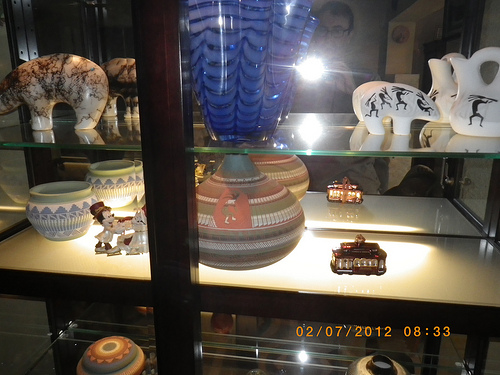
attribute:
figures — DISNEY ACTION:
[22, 51, 484, 160]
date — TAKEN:
[292, 315, 454, 347]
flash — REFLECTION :
[289, 45, 341, 85]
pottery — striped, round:
[192, 155, 303, 286]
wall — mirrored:
[18, 2, 471, 372]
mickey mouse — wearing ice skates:
[90, 199, 127, 258]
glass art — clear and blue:
[186, 1, 316, 140]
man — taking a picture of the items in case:
[290, 1, 380, 111]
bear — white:
[346, 82, 451, 154]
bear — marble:
[16, 52, 115, 151]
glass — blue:
[179, 0, 309, 148]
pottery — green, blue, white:
[12, 175, 103, 245]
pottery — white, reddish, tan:
[188, 152, 304, 273]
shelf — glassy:
[187, 100, 495, 160]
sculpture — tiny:
[92, 200, 121, 253]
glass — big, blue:
[191, 7, 315, 154]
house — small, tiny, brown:
[330, 236, 386, 271]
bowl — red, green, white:
[192, 154, 312, 271]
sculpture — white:
[361, 86, 446, 136]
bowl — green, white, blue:
[22, 182, 97, 246]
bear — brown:
[4, 50, 111, 129]